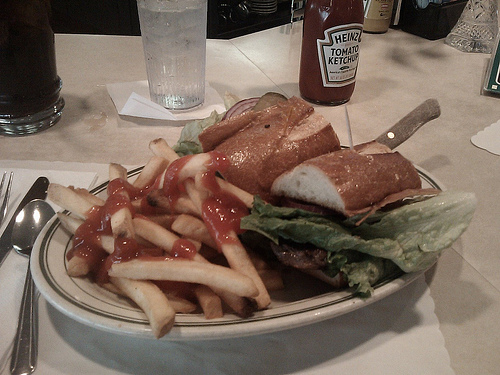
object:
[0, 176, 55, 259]
knife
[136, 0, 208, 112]
glass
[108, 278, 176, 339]
french fries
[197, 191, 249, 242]
ketchup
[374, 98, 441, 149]
knife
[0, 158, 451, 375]
placemat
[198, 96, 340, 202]
food.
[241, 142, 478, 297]
sandswich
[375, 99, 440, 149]
handle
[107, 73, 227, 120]
napkin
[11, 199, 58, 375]
silver spoon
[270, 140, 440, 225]
food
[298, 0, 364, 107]
ketchup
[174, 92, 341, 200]
sandwich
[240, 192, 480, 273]
lettuce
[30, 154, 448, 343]
plate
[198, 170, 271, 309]
french fry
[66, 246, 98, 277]
french fry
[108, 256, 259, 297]
french fry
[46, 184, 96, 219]
french fry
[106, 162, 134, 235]
french fry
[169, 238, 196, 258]
ketchup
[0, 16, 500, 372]
table